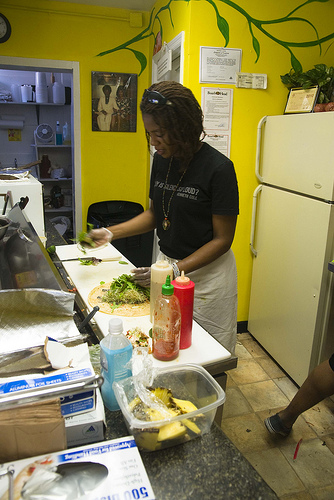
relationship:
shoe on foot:
[246, 390, 281, 436] [247, 388, 331, 465]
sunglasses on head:
[141, 87, 189, 127] [95, 94, 266, 174]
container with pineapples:
[134, 365, 210, 422] [152, 399, 202, 439]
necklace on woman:
[148, 185, 188, 224] [110, 65, 240, 269]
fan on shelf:
[44, 209, 87, 250] [3, 102, 68, 210]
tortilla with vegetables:
[61, 260, 171, 336] [97, 268, 132, 294]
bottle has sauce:
[177, 261, 216, 340] [130, 278, 232, 375]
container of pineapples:
[134, 365, 210, 422] [152, 399, 202, 439]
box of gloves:
[61, 442, 154, 483] [76, 213, 156, 292]